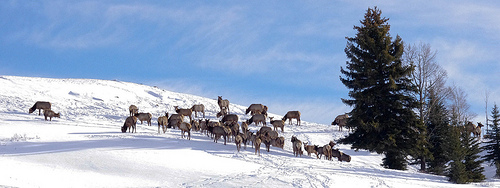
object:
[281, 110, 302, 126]
deer is brown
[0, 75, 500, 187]
snow is in ground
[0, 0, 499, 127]
sky is blue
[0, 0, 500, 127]
clouds are white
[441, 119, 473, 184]
small pine tree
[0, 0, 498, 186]
clear winter day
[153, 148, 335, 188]
hoof prints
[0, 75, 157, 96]
top of the hill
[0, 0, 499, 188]
cold season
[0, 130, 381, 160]
shadow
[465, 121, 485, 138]
moose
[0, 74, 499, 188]
slope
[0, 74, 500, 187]
tracks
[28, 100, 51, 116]
caribou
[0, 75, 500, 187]
snow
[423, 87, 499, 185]
trees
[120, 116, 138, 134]
reindeer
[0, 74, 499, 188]
hillside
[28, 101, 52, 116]
reindeer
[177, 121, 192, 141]
animal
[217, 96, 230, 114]
animal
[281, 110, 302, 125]
animal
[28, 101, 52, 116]
animal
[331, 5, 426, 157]
evergreen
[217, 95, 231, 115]
antelope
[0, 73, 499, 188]
hill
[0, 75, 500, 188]
land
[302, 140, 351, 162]
animals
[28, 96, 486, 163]
herd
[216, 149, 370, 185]
tacks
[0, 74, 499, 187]
ground